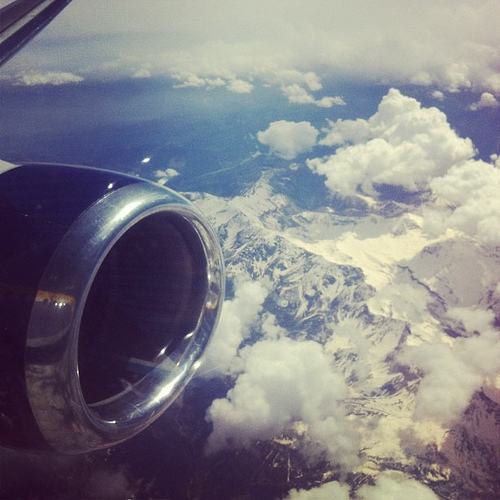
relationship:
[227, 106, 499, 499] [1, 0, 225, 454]
ground below airplane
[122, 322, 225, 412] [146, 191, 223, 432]
reflection on rim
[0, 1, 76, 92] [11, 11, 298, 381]
part of plane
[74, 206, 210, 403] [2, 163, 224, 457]
inside of engine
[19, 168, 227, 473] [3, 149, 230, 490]
trim on engine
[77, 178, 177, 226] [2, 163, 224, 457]
light on engine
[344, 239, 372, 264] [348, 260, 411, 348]
snow on peaks